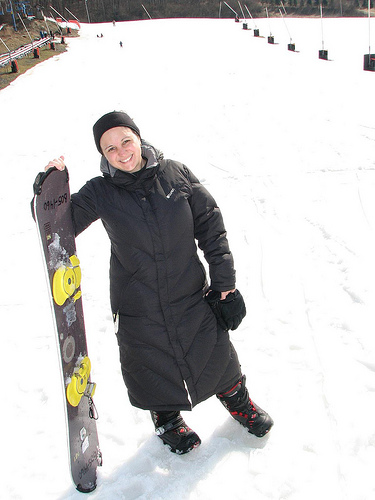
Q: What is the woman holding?
A: Snow board.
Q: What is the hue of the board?
A: Yellow and black.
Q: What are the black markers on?
A: Snow.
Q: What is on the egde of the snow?
A: Dirt and markers.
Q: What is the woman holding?
A: A snowboard.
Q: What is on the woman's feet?
A: Snowboard boots.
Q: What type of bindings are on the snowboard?
A: Step-ins.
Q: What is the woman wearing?
A: A long black coat.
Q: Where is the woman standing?
A: In the snow.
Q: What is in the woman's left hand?
A: Mittens.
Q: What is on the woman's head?
A: A headband.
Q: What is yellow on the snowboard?
A: The bindings.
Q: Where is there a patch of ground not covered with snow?
A: On the left.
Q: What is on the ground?
A: Snow.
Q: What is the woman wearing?
A: Long black coat.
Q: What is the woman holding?
A: Snowboard.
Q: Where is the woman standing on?
A: Snow.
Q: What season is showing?
A: Winter.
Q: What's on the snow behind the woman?
A: Barriers.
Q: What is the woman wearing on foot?
A: Black and red boots.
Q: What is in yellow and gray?
A: Snowboard.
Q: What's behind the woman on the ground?
A: White snow.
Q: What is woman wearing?
A: Black coat.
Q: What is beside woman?
A: Snowboard.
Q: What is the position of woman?
A: Standing.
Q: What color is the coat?
A: Black.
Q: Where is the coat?
A: On woman.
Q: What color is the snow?
A: White.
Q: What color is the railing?
A: Silver.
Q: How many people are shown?
A: One.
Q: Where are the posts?
A: In snow.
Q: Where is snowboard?
A: Beside woman.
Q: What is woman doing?
A: Standing.